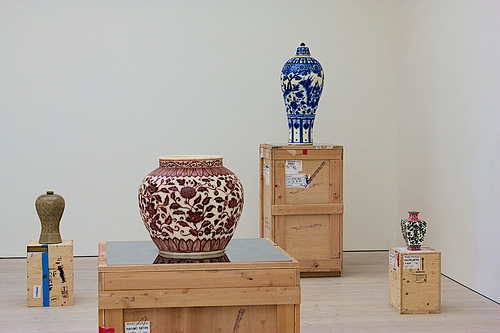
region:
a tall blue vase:
[291, 48, 370, 156]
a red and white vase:
[151, 173, 258, 257]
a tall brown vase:
[39, 195, 95, 240]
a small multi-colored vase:
[399, 210, 440, 267]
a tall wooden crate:
[276, 157, 399, 299]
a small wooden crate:
[395, 250, 455, 304]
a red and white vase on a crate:
[154, 174, 242, 331]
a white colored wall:
[146, 34, 272, 154]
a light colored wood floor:
[353, 301, 375, 328]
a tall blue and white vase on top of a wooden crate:
[279, 34, 351, 267]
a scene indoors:
[5, 2, 497, 331]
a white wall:
[4, 4, 483, 264]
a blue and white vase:
[253, 28, 340, 155]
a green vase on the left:
[20, 177, 82, 254]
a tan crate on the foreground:
[86, 233, 330, 329]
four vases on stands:
[16, 36, 465, 254]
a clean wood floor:
[2, 236, 492, 327]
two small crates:
[2, 242, 463, 314]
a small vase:
[397, 206, 431, 254]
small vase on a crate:
[390, 197, 430, 259]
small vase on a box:
[382, 200, 449, 331]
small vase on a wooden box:
[390, 202, 440, 322]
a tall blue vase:
[280, 29, 323, 155]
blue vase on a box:
[252, 38, 353, 281]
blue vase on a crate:
[254, 27, 356, 284]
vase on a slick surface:
[135, 148, 250, 269]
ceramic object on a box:
[30, 179, 69, 252]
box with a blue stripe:
[15, 233, 78, 315]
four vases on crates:
[24, 35, 464, 287]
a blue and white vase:
[273, 42, 327, 142]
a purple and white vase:
[388, 205, 442, 255]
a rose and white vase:
[129, 145, 242, 260]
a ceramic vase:
[30, 186, 80, 250]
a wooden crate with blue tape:
[23, 242, 78, 314]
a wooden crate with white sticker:
[392, 240, 449, 324]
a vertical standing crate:
[258, 136, 355, 291]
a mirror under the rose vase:
[96, 225, 298, 301]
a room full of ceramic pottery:
[13, 55, 450, 331]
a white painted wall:
[74, 87, 181, 142]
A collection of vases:
[19, 14, 462, 331]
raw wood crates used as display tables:
[253, 136, 348, 284]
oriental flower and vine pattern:
[138, 170, 244, 243]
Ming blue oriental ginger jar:
[278, 34, 327, 151]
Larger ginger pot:
[136, 141, 247, 258]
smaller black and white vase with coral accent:
[393, 203, 442, 255]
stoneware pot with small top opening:
[31, 181, 74, 245]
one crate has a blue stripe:
[35, 238, 59, 310]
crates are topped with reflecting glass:
[90, 235, 299, 277]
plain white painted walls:
[11, 4, 494, 176]